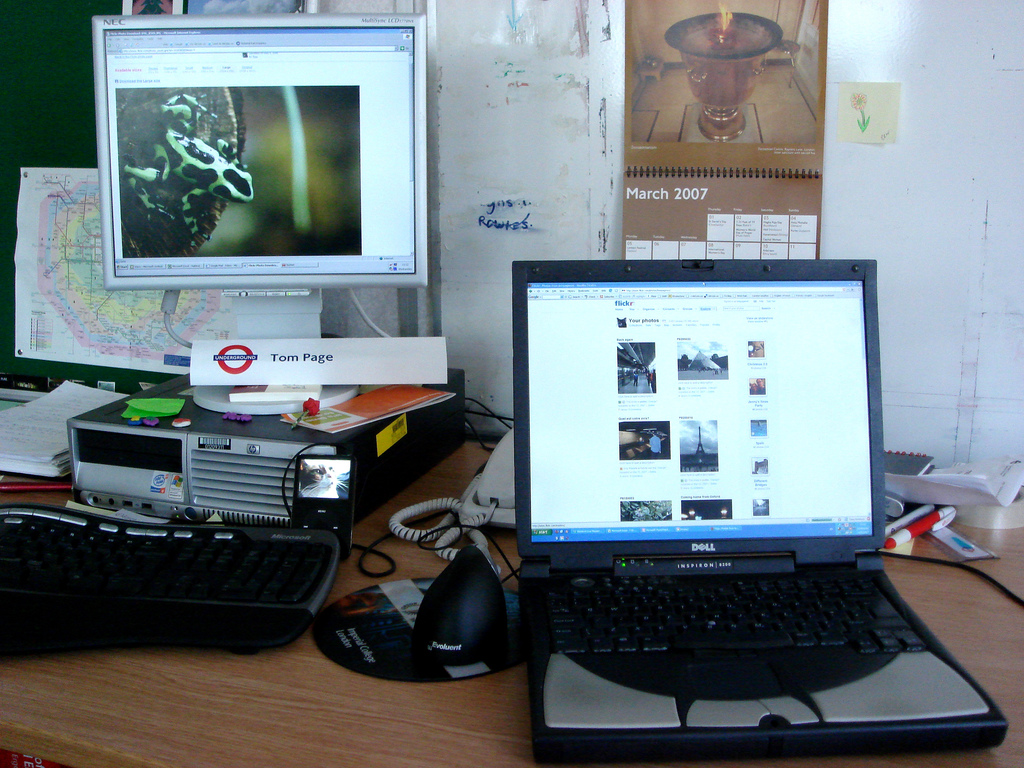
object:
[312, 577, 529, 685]
mouse pad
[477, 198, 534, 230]
note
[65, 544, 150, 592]
keys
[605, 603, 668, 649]
keys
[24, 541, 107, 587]
keys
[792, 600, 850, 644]
keys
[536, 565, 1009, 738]
keyboard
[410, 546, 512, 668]
computer mouse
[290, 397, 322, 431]
flower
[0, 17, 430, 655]
computer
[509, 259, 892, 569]
monitor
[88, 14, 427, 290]
monitor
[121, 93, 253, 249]
frog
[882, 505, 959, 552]
pens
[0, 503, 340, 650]
keyboard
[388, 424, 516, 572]
phone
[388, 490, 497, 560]
cord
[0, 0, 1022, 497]
wall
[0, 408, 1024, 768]
desk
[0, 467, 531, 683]
oddsandends